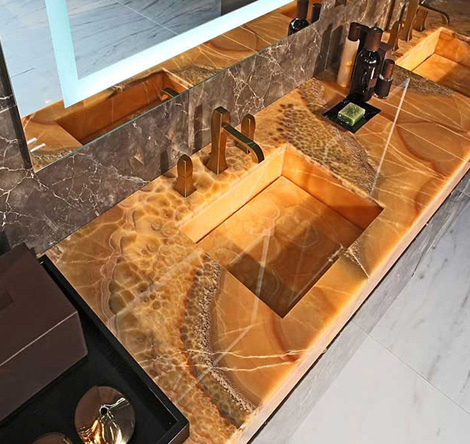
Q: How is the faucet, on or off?
A: Off.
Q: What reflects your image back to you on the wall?
A: Mirror.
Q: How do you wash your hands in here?
A: Sink.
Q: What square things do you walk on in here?
A: Tiles.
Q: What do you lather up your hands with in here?
A: Soap.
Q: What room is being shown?
A: Bathroom.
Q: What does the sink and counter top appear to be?
A: Wood.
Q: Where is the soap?
A: Right side of the sink.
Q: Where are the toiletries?
A: Between the sinks.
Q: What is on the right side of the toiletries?
A: A second sink bowl.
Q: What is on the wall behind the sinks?
A: Mirror.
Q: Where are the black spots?
A: On the floor.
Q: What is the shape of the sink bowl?
A: Rectangle.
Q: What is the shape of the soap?
A: Square.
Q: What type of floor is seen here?
A: Gray marble.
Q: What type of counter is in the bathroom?
A: Orange shaded marble.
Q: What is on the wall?
A: Mirror.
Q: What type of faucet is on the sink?
A: Brass colored faucet.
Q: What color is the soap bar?
A: Green.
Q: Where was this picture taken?
A: A bathroom.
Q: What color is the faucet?
A: Bronze.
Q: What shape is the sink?
A: Rectangle.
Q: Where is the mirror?
A: Above the counter.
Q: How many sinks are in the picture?
A: Two.